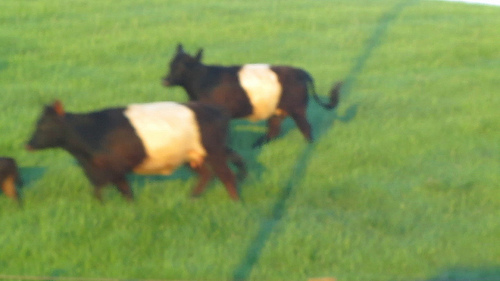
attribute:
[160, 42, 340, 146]
cow — black and white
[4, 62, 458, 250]
cow — black and white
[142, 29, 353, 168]
cow — black and white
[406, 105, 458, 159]
grass — green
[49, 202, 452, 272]
grass — green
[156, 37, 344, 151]
cow — black and white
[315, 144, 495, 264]
grass — green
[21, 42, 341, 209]
cows — black and white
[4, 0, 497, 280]
grass — green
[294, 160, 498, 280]
grass — green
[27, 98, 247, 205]
cow — black and white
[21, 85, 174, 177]
cow — black and white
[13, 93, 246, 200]
cow — black, white, black and white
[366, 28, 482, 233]
grass — green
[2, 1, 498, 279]
field — grassy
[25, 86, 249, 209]
cow — black and white